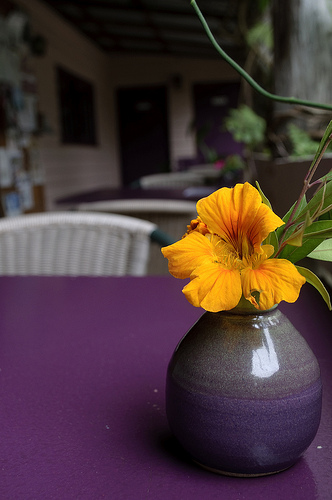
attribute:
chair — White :
[1, 210, 178, 274]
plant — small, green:
[199, 111, 330, 323]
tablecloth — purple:
[57, 183, 232, 209]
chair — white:
[136, 165, 209, 188]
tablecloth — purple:
[44, 267, 156, 342]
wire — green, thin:
[194, 10, 323, 106]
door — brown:
[128, 89, 167, 177]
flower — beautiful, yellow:
[162, 180, 306, 309]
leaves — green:
[255, 119, 330, 311]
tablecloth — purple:
[49, 327, 142, 414]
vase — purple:
[150, 321, 330, 452]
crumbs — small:
[151, 387, 164, 421]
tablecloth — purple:
[1, 268, 330, 497]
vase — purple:
[155, 312, 320, 475]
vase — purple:
[162, 296, 327, 478]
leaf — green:
[248, 175, 279, 253]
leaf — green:
[279, 191, 314, 256]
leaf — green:
[280, 219, 330, 267]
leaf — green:
[286, 176, 331, 244]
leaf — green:
[288, 262, 330, 311]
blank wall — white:
[55, 153, 99, 187]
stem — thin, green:
[191, 3, 330, 110]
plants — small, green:
[223, 107, 276, 172]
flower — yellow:
[156, 176, 312, 318]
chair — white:
[1, 207, 155, 274]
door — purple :
[203, 81, 251, 160]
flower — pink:
[212, 156, 226, 169]